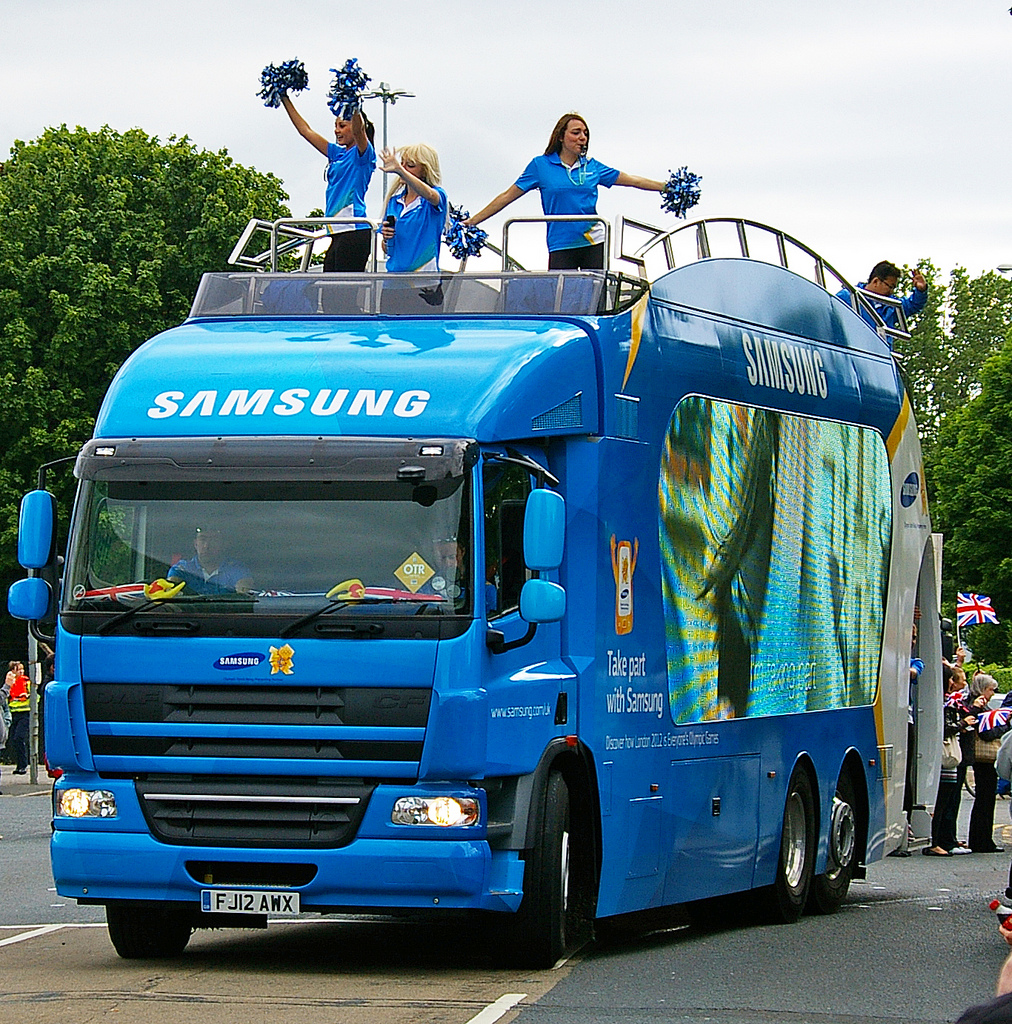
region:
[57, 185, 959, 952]
THE BUS IS BLUE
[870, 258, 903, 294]
THE MAN HAS SHORT HAIR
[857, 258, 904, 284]
THE MAN HAS DARK HAIR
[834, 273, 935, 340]
THE MAN IS WEARING A BLUE JACKET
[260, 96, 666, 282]
THE GIRLS ARE WEARING BLUE AND WHITE SHIRTS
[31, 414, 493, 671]
THE WINDSHIELD IS LARGE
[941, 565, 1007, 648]
THIS IS A FLAG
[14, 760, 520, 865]
THESE ARE HEADLIGHTS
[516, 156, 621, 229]
the shirt is blue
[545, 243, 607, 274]
the pants are black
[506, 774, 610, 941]
the front wheel of the bus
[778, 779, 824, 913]
the middle wheel of the bus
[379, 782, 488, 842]
it is the head light of the bus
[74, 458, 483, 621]
it is the windshield of the bus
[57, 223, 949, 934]
a large blue bus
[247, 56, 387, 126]
blue pom poms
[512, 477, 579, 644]
side mirror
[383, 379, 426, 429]
letter on the bus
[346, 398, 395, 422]
letter on the bus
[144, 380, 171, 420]
letter on the bus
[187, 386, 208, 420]
letter on the bus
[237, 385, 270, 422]
letter on the bus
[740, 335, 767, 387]
letter on the bus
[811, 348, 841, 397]
letter on the bus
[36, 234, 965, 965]
The bus is blue.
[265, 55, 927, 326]
The people on the roof of the bus are wearing blue.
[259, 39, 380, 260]
The woman is holding blue pom poms.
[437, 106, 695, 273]
The woman is holding blue pom poms.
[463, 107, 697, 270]
The woman has a whistle in her mouth.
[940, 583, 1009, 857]
The people are carrying small flags.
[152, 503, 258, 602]
The passenger is wearing sunglasses on his head.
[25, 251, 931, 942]
blue bus on the street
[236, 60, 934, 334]
people on top of the bus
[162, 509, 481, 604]
men riding inside the bus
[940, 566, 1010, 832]
people standing on the street holding flags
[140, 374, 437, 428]
white lettering on the blue bus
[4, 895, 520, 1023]
white lines on the street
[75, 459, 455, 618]
windshield on the bus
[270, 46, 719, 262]
blue and silver pom poms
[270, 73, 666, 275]
women wearing blue shirts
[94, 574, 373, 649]
windshield wipers on the bus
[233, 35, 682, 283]
Cheerleaders on top of the bus.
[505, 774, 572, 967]
black tire is round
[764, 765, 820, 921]
black tire is round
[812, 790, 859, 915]
black tire is round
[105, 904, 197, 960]
black tire is round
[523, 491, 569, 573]
mirror is metal and blue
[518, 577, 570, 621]
mirror is metal and blue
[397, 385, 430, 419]
letter is white and on a bus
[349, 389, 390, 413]
letter is white and on a bus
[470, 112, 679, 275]
person wearing blue tee shirt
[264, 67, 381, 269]
person wearing blue tee shirt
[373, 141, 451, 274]
person wearing blue tee shirt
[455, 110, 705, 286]
woman shaking blue based pom poms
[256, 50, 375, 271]
woman shaking blue based pom poms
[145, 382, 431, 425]
white letters on blue background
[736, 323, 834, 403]
white letters on blue background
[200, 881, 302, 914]
white license plate with black ID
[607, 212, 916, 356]
silver railing on top of large vehicle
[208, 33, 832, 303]
cheerleaders on top of truck